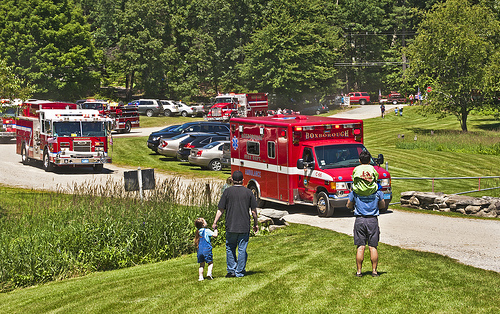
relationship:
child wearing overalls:
[195, 214, 218, 279] [195, 226, 214, 264]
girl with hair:
[351, 149, 375, 196] [359, 147, 371, 164]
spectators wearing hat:
[209, 169, 258, 277] [229, 166, 245, 179]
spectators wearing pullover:
[209, 169, 258, 277] [217, 182, 261, 235]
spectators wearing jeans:
[209, 169, 258, 277] [221, 232, 253, 278]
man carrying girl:
[350, 184, 389, 275] [351, 149, 375, 196]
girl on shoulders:
[351, 149, 375, 196] [349, 188, 384, 201]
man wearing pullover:
[350, 184, 389, 275] [348, 187, 383, 215]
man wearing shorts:
[350, 184, 389, 275] [350, 215, 382, 247]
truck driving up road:
[10, 98, 112, 172] [0, 106, 499, 269]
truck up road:
[10, 98, 112, 172] [0, 106, 499, 269]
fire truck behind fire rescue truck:
[78, 96, 137, 129] [10, 101, 114, 173]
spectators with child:
[209, 169, 258, 277] [195, 214, 218, 279]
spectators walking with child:
[209, 169, 258, 277] [195, 214, 218, 279]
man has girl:
[350, 184, 389, 275] [351, 149, 375, 196]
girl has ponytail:
[351, 144, 382, 196] [360, 147, 368, 156]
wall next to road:
[400, 185, 500, 220] [0, 106, 499, 269]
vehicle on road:
[226, 107, 382, 218] [0, 106, 499, 269]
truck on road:
[11, 97, 110, 172] [0, 106, 499, 269]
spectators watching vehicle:
[193, 150, 384, 280] [226, 107, 382, 218]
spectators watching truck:
[193, 150, 384, 280] [11, 97, 110, 172]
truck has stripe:
[10, 98, 112, 172] [10, 126, 30, 136]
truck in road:
[10, 98, 112, 172] [0, 106, 499, 269]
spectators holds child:
[209, 169, 258, 277] [195, 214, 218, 282]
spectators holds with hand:
[209, 169, 258, 277] [211, 224, 221, 231]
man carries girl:
[350, 184, 389, 275] [351, 149, 375, 196]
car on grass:
[188, 141, 235, 167] [4, 105, 499, 312]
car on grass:
[177, 131, 234, 160] [4, 105, 499, 312]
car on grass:
[158, 129, 218, 158] [4, 105, 499, 312]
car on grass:
[148, 117, 230, 151] [4, 105, 499, 312]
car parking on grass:
[188, 141, 235, 167] [4, 105, 499, 312]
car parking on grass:
[177, 131, 234, 160] [4, 105, 499, 312]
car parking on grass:
[148, 117, 230, 151] [4, 105, 499, 312]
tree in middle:
[385, 3, 499, 140] [8, 75, 499, 201]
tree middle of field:
[385, 3, 499, 140] [8, 81, 492, 304]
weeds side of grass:
[6, 165, 258, 288] [4, 105, 499, 312]